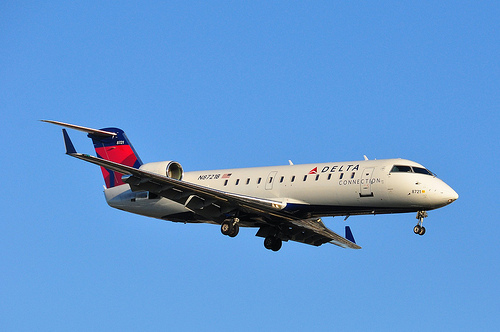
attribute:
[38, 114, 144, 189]
tail — blue, red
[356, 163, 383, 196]
door — on the airplane, of the passengers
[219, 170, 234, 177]
flag — on side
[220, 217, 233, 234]
wheel — black, round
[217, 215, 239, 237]
wheels — down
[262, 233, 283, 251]
wheels — down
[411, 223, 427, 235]
wheels — down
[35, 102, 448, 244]
plane — white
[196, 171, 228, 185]
number — identifying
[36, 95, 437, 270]
plane — of Delta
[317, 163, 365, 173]
delta name — blue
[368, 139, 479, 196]
pilot's cockpit — of the pilot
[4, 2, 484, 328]
sky — clear, bright, blue